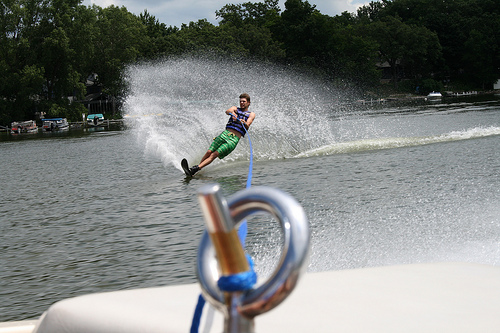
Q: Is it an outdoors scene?
A: Yes, it is outdoors.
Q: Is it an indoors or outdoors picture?
A: It is outdoors.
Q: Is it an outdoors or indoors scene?
A: It is outdoors.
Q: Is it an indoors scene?
A: No, it is outdoors.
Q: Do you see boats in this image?
A: Yes, there is a boat.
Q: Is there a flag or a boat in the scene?
A: Yes, there is a boat.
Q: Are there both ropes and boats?
A: Yes, there are both a boat and a rope.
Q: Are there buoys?
A: No, there are no buoys.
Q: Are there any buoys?
A: No, there are no buoys.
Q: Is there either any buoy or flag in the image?
A: No, there are no buoys or flags.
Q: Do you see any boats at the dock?
A: Yes, there is a boat at the dock.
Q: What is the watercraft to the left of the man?
A: The watercraft is a boat.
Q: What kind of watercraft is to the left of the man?
A: The watercraft is a boat.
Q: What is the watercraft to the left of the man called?
A: The watercraft is a boat.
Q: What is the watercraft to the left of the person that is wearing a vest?
A: The watercraft is a boat.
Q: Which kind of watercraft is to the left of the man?
A: The watercraft is a boat.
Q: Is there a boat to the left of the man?
A: Yes, there is a boat to the left of the man.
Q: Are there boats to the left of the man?
A: Yes, there is a boat to the left of the man.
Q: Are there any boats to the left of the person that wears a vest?
A: Yes, there is a boat to the left of the man.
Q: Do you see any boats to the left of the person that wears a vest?
A: Yes, there is a boat to the left of the man.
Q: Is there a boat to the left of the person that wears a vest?
A: Yes, there is a boat to the left of the man.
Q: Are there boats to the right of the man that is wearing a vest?
A: No, the boat is to the left of the man.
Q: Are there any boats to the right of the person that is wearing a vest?
A: No, the boat is to the left of the man.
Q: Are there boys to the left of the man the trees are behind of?
A: No, there is a boat to the left of the man.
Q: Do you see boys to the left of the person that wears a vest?
A: No, there is a boat to the left of the man.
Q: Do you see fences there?
A: No, there are no fences.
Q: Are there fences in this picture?
A: No, there are no fences.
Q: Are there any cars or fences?
A: No, there are no fences or cars.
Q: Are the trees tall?
A: Yes, the trees are tall.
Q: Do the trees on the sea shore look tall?
A: Yes, the trees are tall.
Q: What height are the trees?
A: The trees are tall.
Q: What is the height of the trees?
A: The trees are tall.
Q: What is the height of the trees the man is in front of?
A: The trees are tall.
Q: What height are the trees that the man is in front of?
A: The trees are tall.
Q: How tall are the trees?
A: The trees are tall.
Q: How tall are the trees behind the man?
A: The trees are tall.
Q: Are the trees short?
A: No, the trees are tall.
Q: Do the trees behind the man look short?
A: No, the trees are tall.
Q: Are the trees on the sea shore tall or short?
A: The trees are tall.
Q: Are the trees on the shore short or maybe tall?
A: The trees are tall.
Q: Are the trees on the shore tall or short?
A: The trees are tall.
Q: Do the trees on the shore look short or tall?
A: The trees are tall.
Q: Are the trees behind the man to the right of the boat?
A: Yes, the trees are behind the man.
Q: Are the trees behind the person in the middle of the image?
A: Yes, the trees are behind the man.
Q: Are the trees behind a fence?
A: No, the trees are behind the man.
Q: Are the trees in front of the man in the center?
A: No, the trees are behind the man.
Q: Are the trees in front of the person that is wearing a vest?
A: No, the trees are behind the man.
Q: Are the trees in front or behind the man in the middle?
A: The trees are behind the man.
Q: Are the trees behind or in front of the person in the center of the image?
A: The trees are behind the man.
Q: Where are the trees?
A: The trees are on the sea shore.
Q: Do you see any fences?
A: No, there are no fences.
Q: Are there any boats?
A: Yes, there is a boat.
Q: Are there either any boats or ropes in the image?
A: Yes, there is a boat.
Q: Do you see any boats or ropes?
A: Yes, there is a boat.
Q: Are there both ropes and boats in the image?
A: Yes, there are both a boat and a rope.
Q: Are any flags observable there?
A: No, there are no flags.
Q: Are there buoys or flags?
A: No, there are no flags or buoys.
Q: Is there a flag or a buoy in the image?
A: No, there are no flags or buoys.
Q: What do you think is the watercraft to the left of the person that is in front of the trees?
A: The watercraft is a boat.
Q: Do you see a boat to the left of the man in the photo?
A: Yes, there is a boat to the left of the man.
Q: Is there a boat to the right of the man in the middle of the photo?
A: No, the boat is to the left of the man.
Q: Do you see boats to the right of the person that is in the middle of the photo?
A: No, the boat is to the left of the man.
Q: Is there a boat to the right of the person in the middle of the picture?
A: No, the boat is to the left of the man.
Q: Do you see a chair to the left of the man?
A: No, there is a boat to the left of the man.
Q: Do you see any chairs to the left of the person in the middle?
A: No, there is a boat to the left of the man.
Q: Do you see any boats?
A: Yes, there is a boat.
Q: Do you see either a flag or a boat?
A: Yes, there is a boat.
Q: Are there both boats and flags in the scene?
A: No, there is a boat but no flags.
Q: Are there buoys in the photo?
A: No, there are no buoys.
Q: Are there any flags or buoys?
A: No, there are no buoys or flags.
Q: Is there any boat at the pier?
A: Yes, there is a boat at the pier.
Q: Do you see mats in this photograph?
A: No, there are no mats.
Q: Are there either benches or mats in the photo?
A: No, there are no mats or benches.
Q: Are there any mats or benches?
A: No, there are no mats or benches.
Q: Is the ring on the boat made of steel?
A: Yes, the ring is made of steel.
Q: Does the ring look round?
A: Yes, the ring is round.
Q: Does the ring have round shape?
A: Yes, the ring is round.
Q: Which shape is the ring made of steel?
A: The ring is round.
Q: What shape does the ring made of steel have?
A: The ring has round shape.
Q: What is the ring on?
A: The ring is on the boat.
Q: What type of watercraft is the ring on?
A: The ring is on the boat.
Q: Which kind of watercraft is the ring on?
A: The ring is on the boat.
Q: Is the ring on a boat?
A: Yes, the ring is on a boat.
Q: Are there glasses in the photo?
A: No, there are no glasses.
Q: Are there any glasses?
A: No, there are no glasses.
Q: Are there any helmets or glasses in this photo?
A: No, there are no glasses or helmets.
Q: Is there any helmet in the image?
A: No, there are no helmets.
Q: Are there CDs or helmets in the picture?
A: No, there are no helmets or cds.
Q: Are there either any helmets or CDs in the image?
A: No, there are no helmets or cds.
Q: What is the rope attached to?
A: The rope is attached to the boat.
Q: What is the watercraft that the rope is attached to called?
A: The watercraft is a boat.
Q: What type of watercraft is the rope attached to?
A: The rope is attached to the boat.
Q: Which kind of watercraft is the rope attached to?
A: The rope is attached to the boat.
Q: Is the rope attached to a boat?
A: Yes, the rope is attached to a boat.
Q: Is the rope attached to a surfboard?
A: No, the rope is attached to a boat.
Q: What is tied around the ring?
A: The rope is tied around the ring.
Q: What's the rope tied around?
A: The rope is tied around the ring.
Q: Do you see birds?
A: No, there are no birds.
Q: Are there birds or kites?
A: No, there are no birds or kites.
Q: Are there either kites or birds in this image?
A: No, there are no birds or kites.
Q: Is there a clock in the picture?
A: No, there are no clocks.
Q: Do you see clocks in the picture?
A: No, there are no clocks.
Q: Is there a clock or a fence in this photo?
A: No, there are no clocks or fences.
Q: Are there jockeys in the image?
A: No, there are no jockeys.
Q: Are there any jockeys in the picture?
A: No, there are no jockeys.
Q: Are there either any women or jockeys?
A: No, there are no jockeys or women.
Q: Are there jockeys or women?
A: No, there are no jockeys or women.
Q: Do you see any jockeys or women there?
A: No, there are no jockeys or women.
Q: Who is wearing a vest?
A: The man is wearing a vest.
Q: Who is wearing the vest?
A: The man is wearing a vest.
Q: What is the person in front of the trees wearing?
A: The man is wearing a vest.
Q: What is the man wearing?
A: The man is wearing a vest.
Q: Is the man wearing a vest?
A: Yes, the man is wearing a vest.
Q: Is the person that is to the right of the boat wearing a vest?
A: Yes, the man is wearing a vest.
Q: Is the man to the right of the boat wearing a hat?
A: No, the man is wearing a vest.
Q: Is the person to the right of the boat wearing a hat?
A: No, the man is wearing a vest.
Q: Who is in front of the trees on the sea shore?
A: The man is in front of the trees.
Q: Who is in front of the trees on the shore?
A: The man is in front of the trees.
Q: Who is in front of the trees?
A: The man is in front of the trees.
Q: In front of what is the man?
A: The man is in front of the trees.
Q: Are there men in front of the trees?
A: Yes, there is a man in front of the trees.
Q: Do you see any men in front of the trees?
A: Yes, there is a man in front of the trees.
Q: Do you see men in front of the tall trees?
A: Yes, there is a man in front of the trees.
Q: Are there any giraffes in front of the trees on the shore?
A: No, there is a man in front of the trees.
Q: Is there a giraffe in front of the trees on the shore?
A: No, there is a man in front of the trees.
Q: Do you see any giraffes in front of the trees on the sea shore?
A: No, there is a man in front of the trees.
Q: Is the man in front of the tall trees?
A: Yes, the man is in front of the trees.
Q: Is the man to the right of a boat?
A: Yes, the man is to the right of a boat.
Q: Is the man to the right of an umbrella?
A: No, the man is to the right of a boat.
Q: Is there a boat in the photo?
A: Yes, there is a boat.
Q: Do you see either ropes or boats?
A: Yes, there is a boat.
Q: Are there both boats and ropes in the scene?
A: Yes, there are both a boat and a rope.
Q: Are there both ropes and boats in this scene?
A: Yes, there are both a boat and a rope.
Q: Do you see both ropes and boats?
A: Yes, there are both a boat and a rope.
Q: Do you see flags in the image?
A: No, there are no flags.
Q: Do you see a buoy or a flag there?
A: No, there are no flags or buoys.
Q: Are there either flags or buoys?
A: No, there are no flags or buoys.